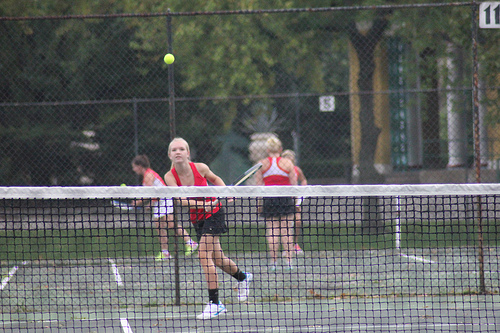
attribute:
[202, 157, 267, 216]
racket — short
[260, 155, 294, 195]
tank top — red 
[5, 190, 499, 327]
tennis net — white, black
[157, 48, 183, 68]
tennis ball — green , small 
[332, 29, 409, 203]
column — brown, building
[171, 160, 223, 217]
top — red 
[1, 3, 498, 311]
fences — large 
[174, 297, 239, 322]
shoe — white 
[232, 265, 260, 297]
shoe — white 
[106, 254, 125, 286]
pole — long, white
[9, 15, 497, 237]
fence — black 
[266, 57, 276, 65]
leaf — green 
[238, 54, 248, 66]
leaf — green 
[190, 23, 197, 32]
leaf — green 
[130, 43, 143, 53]
leaf — green 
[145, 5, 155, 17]
leaf — green 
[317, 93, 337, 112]
tag — white 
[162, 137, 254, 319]
girl — red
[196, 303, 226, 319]
shoe — white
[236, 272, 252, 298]
shoe — white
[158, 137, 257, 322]
person — playing tennis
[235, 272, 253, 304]
shoe — white 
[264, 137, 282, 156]
hair — blonde 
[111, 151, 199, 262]
person — playing tennis